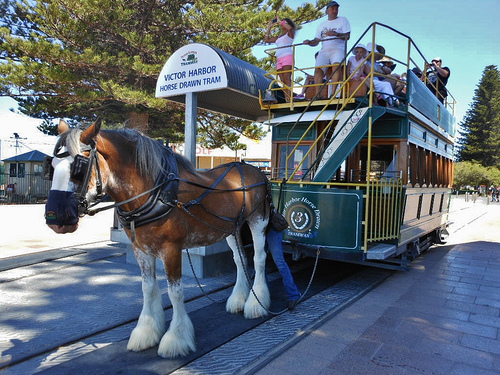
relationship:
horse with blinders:
[61, 125, 271, 345] [71, 154, 94, 184]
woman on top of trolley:
[266, 12, 298, 108] [265, 38, 455, 254]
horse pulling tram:
[61, 125, 271, 345] [265, 38, 455, 254]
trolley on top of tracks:
[265, 38, 455, 254] [43, 256, 362, 374]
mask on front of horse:
[48, 185, 87, 224] [61, 125, 271, 345]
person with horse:
[241, 165, 298, 303] [61, 125, 271, 345]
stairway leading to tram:
[312, 84, 370, 183] [265, 38, 455, 254]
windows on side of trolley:
[364, 144, 449, 186] [265, 38, 455, 254]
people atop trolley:
[273, 27, 458, 112] [265, 38, 455, 254]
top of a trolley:
[268, 48, 456, 138] [265, 38, 455, 254]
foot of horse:
[159, 324, 194, 355] [61, 125, 271, 345]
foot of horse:
[130, 321, 161, 349] [61, 125, 271, 345]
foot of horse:
[222, 284, 247, 315] [61, 125, 271, 345]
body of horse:
[124, 161, 275, 246] [61, 125, 271, 345]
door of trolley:
[359, 178, 404, 245] [265, 38, 455, 254]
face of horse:
[46, 133, 104, 237] [61, 125, 271, 345]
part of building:
[4, 160, 41, 194] [8, 144, 54, 201]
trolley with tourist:
[265, 38, 455, 254] [309, 7, 349, 111]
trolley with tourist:
[265, 38, 455, 254] [273, 27, 458, 112]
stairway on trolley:
[312, 84, 370, 183] [265, 38, 455, 254]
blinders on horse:
[71, 154, 94, 184] [61, 125, 271, 345]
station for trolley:
[160, 33, 275, 181] [265, 38, 455, 254]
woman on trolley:
[266, 12, 298, 108] [265, 38, 455, 254]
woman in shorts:
[266, 12, 298, 108] [274, 57, 295, 66]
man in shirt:
[418, 55, 448, 112] [427, 69, 449, 97]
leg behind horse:
[266, 235, 310, 298] [61, 125, 271, 345]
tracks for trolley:
[43, 256, 362, 374] [265, 38, 455, 254]